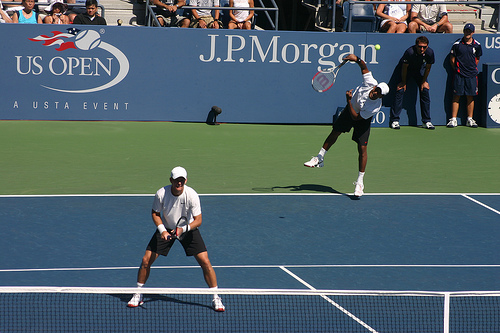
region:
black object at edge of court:
[193, 96, 250, 136]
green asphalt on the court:
[18, 139, 158, 174]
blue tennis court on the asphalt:
[239, 202, 398, 288]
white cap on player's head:
[158, 155, 210, 187]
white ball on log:
[71, 25, 106, 55]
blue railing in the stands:
[178, 3, 302, 36]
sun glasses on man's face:
[408, 36, 441, 61]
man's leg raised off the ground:
[273, 121, 355, 191]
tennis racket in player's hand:
[163, 208, 237, 260]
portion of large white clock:
[478, 92, 495, 132]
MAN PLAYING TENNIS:
[125, 166, 225, 321]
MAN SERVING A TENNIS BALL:
[302, 43, 392, 200]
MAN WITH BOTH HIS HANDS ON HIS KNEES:
[385, 37, 436, 134]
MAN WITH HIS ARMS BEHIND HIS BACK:
[443, 22, 482, 129]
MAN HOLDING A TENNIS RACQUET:
[300, 48, 387, 199]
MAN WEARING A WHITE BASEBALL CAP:
[128, 163, 226, 320]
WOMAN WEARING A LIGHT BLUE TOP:
[11, 0, 43, 25]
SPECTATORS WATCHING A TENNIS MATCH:
[0, 0, 497, 23]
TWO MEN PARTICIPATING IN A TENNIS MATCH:
[118, 49, 393, 311]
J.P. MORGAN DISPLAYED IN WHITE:
[194, 31, 382, 78]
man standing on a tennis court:
[125, 164, 227, 312]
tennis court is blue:
[2, 190, 498, 331]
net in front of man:
[0, 286, 499, 331]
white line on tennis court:
[0, 264, 282, 274]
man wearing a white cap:
[167, 164, 187, 180]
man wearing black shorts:
[147, 223, 207, 256]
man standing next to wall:
[440, 23, 482, 126]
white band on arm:
[156, 222, 165, 234]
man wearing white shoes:
[127, 292, 145, 307]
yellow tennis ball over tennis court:
[372, 42, 381, 51]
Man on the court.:
[120, 137, 257, 329]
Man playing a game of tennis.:
[111, 159, 270, 321]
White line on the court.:
[223, 231, 295, 274]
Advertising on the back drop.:
[193, 23, 397, 80]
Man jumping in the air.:
[279, 36, 438, 220]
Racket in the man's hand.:
[271, 42, 352, 107]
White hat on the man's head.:
[120, 135, 232, 192]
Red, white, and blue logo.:
[30, 17, 106, 60]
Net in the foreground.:
[212, 260, 339, 330]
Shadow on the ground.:
[257, 160, 349, 217]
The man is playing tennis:
[307, 32, 399, 205]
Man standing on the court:
[118, 153, 240, 313]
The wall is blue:
[16, 17, 471, 136]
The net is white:
[3, 275, 488, 327]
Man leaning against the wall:
[389, 30, 446, 140]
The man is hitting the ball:
[304, 33, 397, 222]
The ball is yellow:
[363, 35, 385, 58]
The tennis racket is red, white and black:
[308, 44, 348, 95]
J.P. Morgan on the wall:
[190, 20, 392, 87]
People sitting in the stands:
[22, 2, 276, 40]